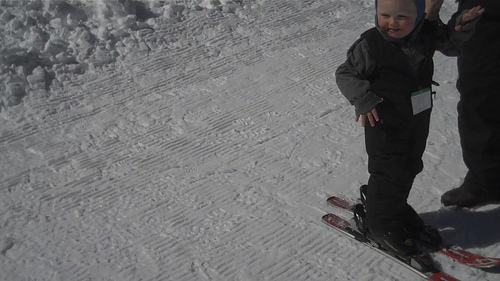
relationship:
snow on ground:
[8, 0, 485, 267] [3, 2, 497, 279]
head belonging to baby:
[374, 1, 426, 42] [298, 3, 488, 278]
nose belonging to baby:
[385, 16, 398, 27] [332, 0, 483, 255]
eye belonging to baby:
[380, 11, 391, 18] [332, 0, 483, 255]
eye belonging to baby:
[397, 14, 408, 20] [332, 0, 483, 255]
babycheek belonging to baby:
[376, 17, 386, 29] [332, 0, 483, 255]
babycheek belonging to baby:
[398, 21, 413, 28] [332, 0, 483, 255]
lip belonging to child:
[387, 25, 403, 30] [333, 0, 485, 260]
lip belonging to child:
[387, 29, 402, 33] [333, 0, 485, 260]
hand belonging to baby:
[352, 107, 379, 127] [332, 0, 483, 255]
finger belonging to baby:
[370, 109, 383, 123] [332, 0, 483, 255]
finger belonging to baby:
[366, 112, 376, 129] [332, 0, 483, 255]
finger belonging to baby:
[361, 114, 366, 127] [332, 0, 483, 255]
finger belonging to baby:
[370, 108, 380, 123] [332, 0, 483, 255]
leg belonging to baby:
[363, 115, 419, 228] [332, 0, 483, 255]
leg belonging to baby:
[390, 117, 431, 217] [332, 0, 483, 255]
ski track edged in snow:
[0, 10, 373, 142] [207, 200, 353, 244]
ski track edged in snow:
[0, 4, 376, 145] [207, 200, 353, 244]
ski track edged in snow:
[286, 198, 335, 224] [207, 200, 353, 244]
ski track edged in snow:
[311, 185, 330, 201] [207, 200, 353, 244]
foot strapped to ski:
[362, 220, 417, 256] [320, 210, 460, 279]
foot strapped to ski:
[360, 183, 447, 251] [320, 212, 459, 281]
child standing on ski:
[333, 0, 441, 262] [320, 212, 459, 281]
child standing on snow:
[333, 0, 441, 262] [8, 0, 485, 267]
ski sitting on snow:
[320, 210, 460, 279] [8, 0, 485, 267]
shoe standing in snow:
[440, 180, 497, 206] [22, 17, 171, 102]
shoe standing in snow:
[440, 184, 500, 211] [22, 17, 171, 102]